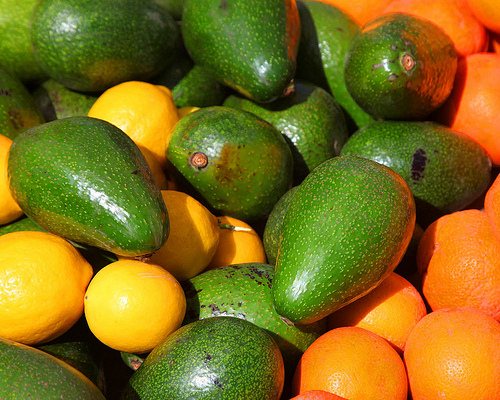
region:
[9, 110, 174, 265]
The avocado is green.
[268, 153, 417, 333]
The avocado is green.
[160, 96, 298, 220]
The avocado is green.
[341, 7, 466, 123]
The avocado is green.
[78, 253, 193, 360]
The lemon is yellow.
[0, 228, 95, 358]
The lemon is yellow.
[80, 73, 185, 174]
The lemon is yellow.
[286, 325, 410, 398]
The orange is orange.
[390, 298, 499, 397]
The orange is orange.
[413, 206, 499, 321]
The orange is orange.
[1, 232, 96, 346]
The closest lemon to the camera.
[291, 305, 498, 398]
Two almost fully visible oranges on the bottom right.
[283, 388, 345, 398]
Barely visible top of an orange on the bottom right.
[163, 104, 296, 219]
The middle most green fruit with round brown stem mark.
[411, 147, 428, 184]
Largest black blemish on a green right side fruit.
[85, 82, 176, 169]
A yellow top most lemon.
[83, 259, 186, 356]
The smoothest roundest yellow fruit.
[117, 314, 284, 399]
Bottom most middle green fruit.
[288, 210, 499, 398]
All of the orange on the bottom right under the two green fruits.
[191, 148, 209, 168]
Brown round stem mark on the middle most green fruit.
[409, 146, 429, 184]
a black spot on an avocado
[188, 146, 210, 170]
the stem end of an avocado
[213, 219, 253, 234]
a broken stem on a lemon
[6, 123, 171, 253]
a green avocado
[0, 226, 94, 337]
a yellow lemon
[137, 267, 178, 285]
a scar on a lemon rind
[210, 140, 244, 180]
a brown bruise on an avocad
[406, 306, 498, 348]
white spotting on an orange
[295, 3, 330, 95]
the shadow of one avocado on another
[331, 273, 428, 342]
an orange under an avocado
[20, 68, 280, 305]
green and red fruit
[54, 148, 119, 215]
light hitting the green food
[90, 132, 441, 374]
yellow, green and orange food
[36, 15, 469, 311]
pile of fruit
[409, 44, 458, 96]
reflection on the fruit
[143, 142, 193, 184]
shadow on the food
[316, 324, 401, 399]
one piece of food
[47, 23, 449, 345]
light and shadow hitting fruit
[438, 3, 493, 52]
orange fruit in corner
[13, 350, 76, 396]
green fruit in bottom left corner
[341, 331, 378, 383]
part of an orange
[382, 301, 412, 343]
[art of an orange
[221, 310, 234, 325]
part of an avocado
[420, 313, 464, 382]
part of an orange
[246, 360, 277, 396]
part of a peel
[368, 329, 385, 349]
part of an orange